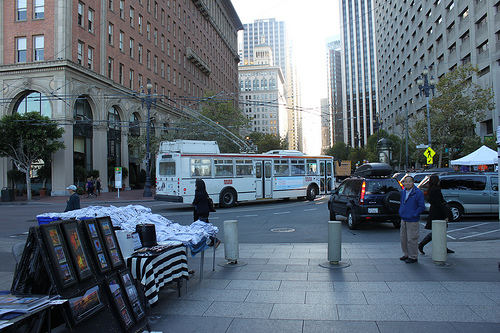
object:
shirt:
[404, 186, 414, 204]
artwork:
[121, 273, 149, 321]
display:
[11, 216, 179, 333]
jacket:
[398, 184, 427, 223]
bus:
[155, 139, 337, 208]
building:
[236, 16, 300, 155]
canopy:
[450, 145, 498, 166]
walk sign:
[423, 147, 436, 158]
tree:
[0, 110, 67, 202]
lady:
[418, 174, 455, 255]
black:
[427, 187, 445, 205]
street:
[0, 194, 500, 243]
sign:
[427, 158, 434, 165]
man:
[63, 184, 81, 213]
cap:
[66, 184, 78, 190]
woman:
[192, 177, 223, 249]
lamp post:
[140, 81, 159, 197]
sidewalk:
[0, 237, 500, 333]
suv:
[327, 162, 406, 229]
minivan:
[414, 174, 500, 221]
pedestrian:
[397, 176, 426, 265]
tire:
[219, 188, 236, 208]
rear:
[152, 138, 255, 209]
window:
[77, 38, 85, 66]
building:
[0, 0, 251, 196]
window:
[86, 44, 94, 71]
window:
[109, 55, 115, 81]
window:
[119, 61, 125, 84]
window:
[129, 67, 134, 90]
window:
[137, 73, 143, 92]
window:
[77, 0, 86, 30]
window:
[87, 6, 96, 36]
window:
[108, 21, 115, 49]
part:
[152, 245, 190, 291]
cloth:
[123, 241, 190, 309]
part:
[406, 221, 420, 260]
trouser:
[400, 219, 420, 260]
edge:
[239, 242, 329, 245]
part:
[351, 263, 500, 333]